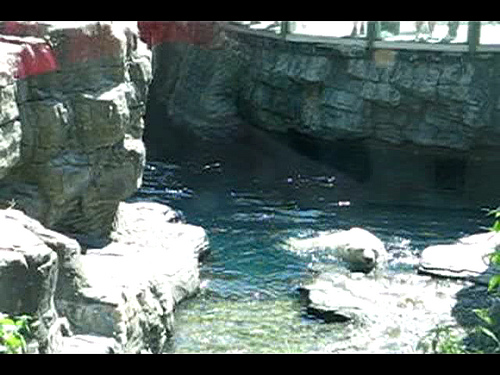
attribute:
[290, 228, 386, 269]
polar bear — at a zoo, in water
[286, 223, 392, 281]
polar bear — at a zoo, in water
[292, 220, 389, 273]
polar bear — at a zoo, in water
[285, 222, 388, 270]
polar bear — white, in water, at a zoo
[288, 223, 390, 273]
polar bear — in water, at a zoo, in the zoo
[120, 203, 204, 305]
ledge — in a zoo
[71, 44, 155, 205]
cliff — in a zoo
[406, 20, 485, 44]
legs — of some people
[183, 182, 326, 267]
water — trickling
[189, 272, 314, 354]
water — blue, green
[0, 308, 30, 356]
foliage — green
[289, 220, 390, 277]
polar bear — at a zoo, in water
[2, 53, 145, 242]
rock — brown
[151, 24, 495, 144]
rock — brown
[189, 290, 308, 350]
water — shallow